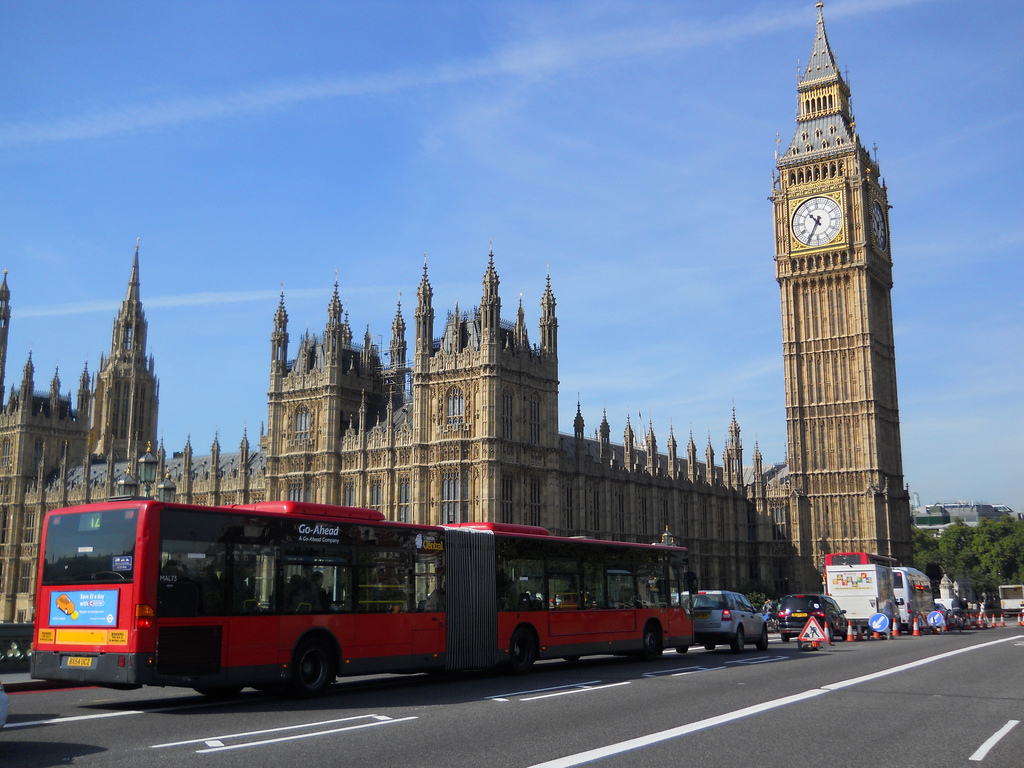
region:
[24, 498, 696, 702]
long red bus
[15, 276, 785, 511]
old brown building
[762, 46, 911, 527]
clock tower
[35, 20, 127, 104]
white clouds in the blue sky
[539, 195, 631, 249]
white clouds in the blue sky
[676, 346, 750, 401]
white clouds in the blue sky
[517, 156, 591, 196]
white clouds in the blue sky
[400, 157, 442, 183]
white clouds in the blue sky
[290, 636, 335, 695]
black rubber tire on bus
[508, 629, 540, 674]
black rubber tire on bus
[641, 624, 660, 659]
black rubber tire on bus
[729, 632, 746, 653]
black rubber tire on car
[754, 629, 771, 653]
black rubber tire on car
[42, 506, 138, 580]
large tinted window on a bus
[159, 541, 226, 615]
large tinted window on a bus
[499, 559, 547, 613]
large tinted window on a bus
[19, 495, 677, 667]
red bus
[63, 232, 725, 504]
large brown building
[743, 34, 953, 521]
brown clock tower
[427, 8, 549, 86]
white clouds in the blue sky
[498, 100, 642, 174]
white clouds in the blue sky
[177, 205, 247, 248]
white clouds in the blue sky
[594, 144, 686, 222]
white clouds in the blue sky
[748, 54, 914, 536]
tan clock tower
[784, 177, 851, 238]
clock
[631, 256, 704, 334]
white clouds in the blue sky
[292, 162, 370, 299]
white clouds in the blue sky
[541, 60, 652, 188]
white clouds in the blue sky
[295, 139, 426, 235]
white clouds in the blue sky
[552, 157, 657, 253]
white clouds in the blue sky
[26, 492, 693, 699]
A red bus driving down the road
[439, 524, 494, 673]
A connector between two bus parts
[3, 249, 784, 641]
The Parliament building in London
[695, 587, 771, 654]
A car stopped in traffic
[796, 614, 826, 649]
A men at work sign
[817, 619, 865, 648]
A grouping of traffic cones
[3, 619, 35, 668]
A section of bridge railing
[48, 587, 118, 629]
A sign pasted on the back of the bus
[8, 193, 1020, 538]
The blue cloudy sky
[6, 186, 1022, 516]
A blue cloudy sky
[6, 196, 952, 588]
The brown building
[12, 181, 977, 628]
A large brown building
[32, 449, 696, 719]
The red passenger bus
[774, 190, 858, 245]
The clock on the building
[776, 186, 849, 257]
A clock to the building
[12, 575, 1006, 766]
The black paved road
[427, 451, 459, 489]
a window on the building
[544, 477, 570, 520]
a window on the building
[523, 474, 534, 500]
a window on the building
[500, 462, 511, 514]
a window on the building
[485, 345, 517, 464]
a window on the building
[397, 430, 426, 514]
a window on the building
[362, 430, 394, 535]
a window on the building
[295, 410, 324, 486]
a window on the building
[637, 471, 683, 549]
a window on the building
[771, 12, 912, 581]
Elizabeth tower in London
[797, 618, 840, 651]
a sign warning road work ahead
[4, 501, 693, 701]
Double long commuter bus with large windows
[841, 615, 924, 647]
orange and white pylons on the road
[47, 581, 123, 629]
blue advertising poster on rear of bus